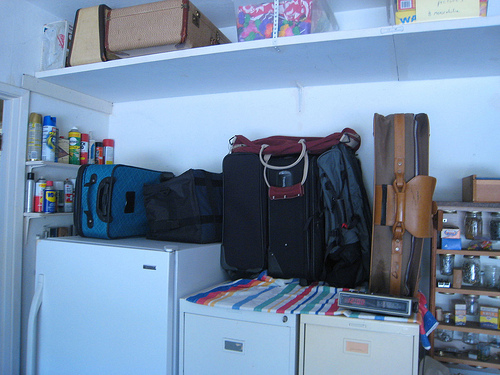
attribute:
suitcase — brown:
[367, 92, 436, 289]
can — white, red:
[30, 175, 48, 215]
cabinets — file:
[173, 272, 425, 372]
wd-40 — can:
[42, 180, 58, 216]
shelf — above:
[33, 19, 498, 95]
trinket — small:
[464, 210, 481, 240]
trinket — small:
[467, 236, 492, 250]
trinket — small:
[435, 277, 452, 287]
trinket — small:
[443, 309, 451, 326]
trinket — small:
[475, 269, 487, 286]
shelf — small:
[428, 202, 498, 368]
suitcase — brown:
[105, 0, 232, 61]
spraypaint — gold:
[22, 108, 43, 163]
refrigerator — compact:
[39, 221, 186, 355]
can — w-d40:
[41, 175, 56, 213]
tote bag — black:
[73, 162, 173, 241]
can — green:
[23, 182, 375, 315]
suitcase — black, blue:
[68, 161, 176, 239]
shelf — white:
[25, 16, 497, 104]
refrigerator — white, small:
[19, 230, 179, 374]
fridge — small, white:
[32, 234, 189, 365]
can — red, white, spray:
[30, 173, 51, 214]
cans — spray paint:
[26, 110, 116, 162]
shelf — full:
[19, 157, 80, 177]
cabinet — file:
[177, 272, 300, 372]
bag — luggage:
[366, 110, 435, 302]